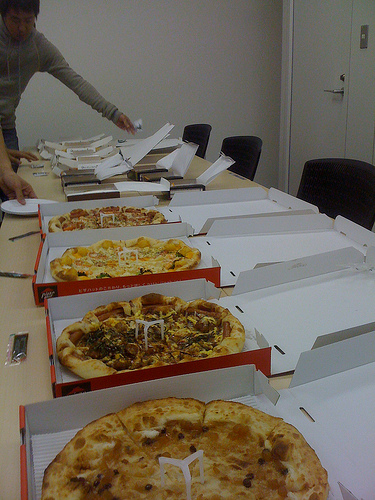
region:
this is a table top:
[9, 120, 352, 488]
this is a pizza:
[40, 277, 244, 377]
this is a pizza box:
[39, 257, 369, 400]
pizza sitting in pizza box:
[30, 238, 369, 394]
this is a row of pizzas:
[34, 112, 338, 497]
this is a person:
[8, 42, 147, 223]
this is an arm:
[25, 41, 183, 164]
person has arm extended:
[21, 32, 175, 160]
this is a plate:
[0, 168, 55, 249]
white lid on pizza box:
[186, 192, 338, 305]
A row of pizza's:
[42, 209, 281, 487]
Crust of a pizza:
[210, 401, 266, 423]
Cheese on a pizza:
[209, 439, 233, 460]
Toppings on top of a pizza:
[96, 333, 127, 357]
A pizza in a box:
[14, 393, 304, 490]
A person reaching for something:
[7, 5, 143, 138]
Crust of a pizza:
[58, 331, 72, 357]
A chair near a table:
[184, 121, 215, 133]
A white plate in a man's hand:
[3, 195, 34, 213]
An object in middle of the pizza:
[156, 451, 205, 496]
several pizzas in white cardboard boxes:
[8, 190, 369, 499]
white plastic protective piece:
[155, 449, 213, 497]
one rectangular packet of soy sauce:
[6, 327, 31, 369]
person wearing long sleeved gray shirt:
[0, 1, 135, 135]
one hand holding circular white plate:
[4, 174, 56, 217]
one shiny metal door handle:
[319, 83, 346, 98]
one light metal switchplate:
[357, 21, 372, 50]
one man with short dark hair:
[1, 0, 41, 44]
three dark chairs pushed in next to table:
[180, 120, 374, 238]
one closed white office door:
[274, 3, 355, 156]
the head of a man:
[4, 0, 51, 47]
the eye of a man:
[7, 11, 50, 31]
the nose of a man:
[9, 13, 34, 36]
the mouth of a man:
[4, 24, 36, 52]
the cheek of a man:
[4, 20, 29, 42]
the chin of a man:
[7, 21, 54, 53]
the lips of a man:
[10, 15, 44, 49]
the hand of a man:
[109, 96, 151, 142]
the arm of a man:
[36, 11, 150, 132]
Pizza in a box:
[43, 411, 321, 499]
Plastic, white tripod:
[148, 449, 213, 498]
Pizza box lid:
[239, 253, 372, 345]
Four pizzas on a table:
[34, 194, 280, 487]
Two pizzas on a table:
[46, 206, 192, 279]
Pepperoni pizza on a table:
[44, 178, 170, 223]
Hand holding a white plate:
[3, 154, 45, 215]